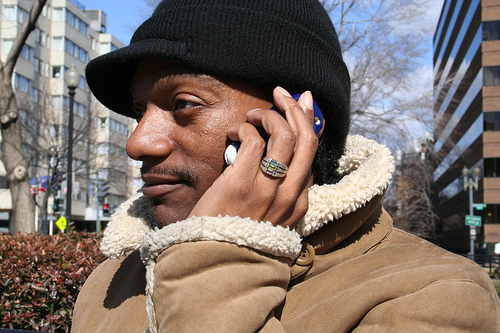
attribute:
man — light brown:
[69, 1, 498, 331]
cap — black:
[84, 0, 354, 142]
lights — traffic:
[88, 174, 109, 225]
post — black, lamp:
[51, 73, 76, 226]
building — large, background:
[0, 1, 152, 238]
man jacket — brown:
[66, 17, 498, 332]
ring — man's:
[259, 155, 286, 180]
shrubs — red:
[3, 232, 120, 330]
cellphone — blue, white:
[292, 91, 340, 147]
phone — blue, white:
[232, 105, 364, 192]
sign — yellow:
[55, 215, 70, 235]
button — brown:
[294, 238, 319, 268]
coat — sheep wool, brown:
[73, 134, 498, 330]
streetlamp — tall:
[34, 36, 86, 223]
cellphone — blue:
[310, 105, 325, 132]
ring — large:
[257, 157, 291, 177]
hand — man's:
[186, 82, 326, 228]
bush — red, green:
[6, 235, 71, 331]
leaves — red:
[42, 245, 50, 257]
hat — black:
[83, 1, 351, 150]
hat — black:
[185, 41, 373, 102]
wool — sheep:
[313, 141, 392, 215]